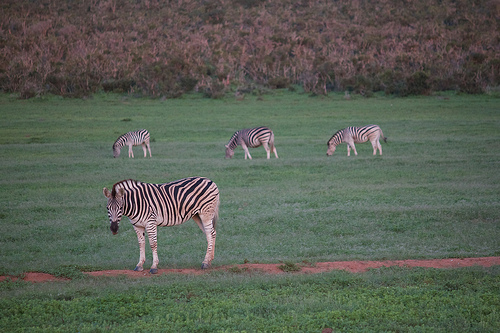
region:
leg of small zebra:
[128, 217, 148, 277]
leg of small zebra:
[142, 219, 162, 271]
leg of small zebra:
[187, 205, 219, 273]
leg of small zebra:
[366, 135, 383, 164]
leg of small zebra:
[337, 131, 362, 160]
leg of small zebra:
[256, 135, 291, 162]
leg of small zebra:
[229, 138, 261, 173]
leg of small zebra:
[136, 136, 157, 158]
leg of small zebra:
[122, 135, 138, 164]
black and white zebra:
[86, 163, 232, 282]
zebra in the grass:
[102, 164, 235, 274]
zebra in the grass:
[213, 117, 300, 167]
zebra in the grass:
[107, 119, 158, 153]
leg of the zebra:
[148, 238, 169, 275]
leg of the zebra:
[194, 238, 224, 279]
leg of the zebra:
[128, 250, 148, 271]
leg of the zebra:
[241, 148, 253, 159]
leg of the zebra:
[344, 142, 360, 160]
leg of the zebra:
[374, 145, 383, 160]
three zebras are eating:
[76, 95, 408, 176]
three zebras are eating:
[100, 109, 407, 164]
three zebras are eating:
[75, 98, 412, 178]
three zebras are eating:
[87, 110, 422, 180]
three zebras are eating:
[53, 101, 405, 163]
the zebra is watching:
[70, 154, 255, 303]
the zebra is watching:
[61, 162, 271, 310]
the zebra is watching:
[76, 166, 251, 293]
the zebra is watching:
[62, 149, 257, 320]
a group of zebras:
[102, 99, 392, 287]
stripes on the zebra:
[92, 176, 242, 268]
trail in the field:
[28, 249, 485, 303]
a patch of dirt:
[10, 260, 67, 295]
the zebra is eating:
[100, 120, 160, 162]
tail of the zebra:
[378, 130, 392, 151]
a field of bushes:
[8, 3, 476, 120]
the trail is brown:
[57, 249, 499, 281]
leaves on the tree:
[401, 58, 428, 78]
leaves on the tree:
[384, 28, 411, 60]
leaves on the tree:
[352, 75, 392, 94]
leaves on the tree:
[313, 32, 353, 71]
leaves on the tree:
[287, 35, 317, 70]